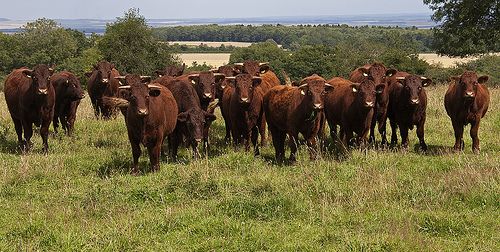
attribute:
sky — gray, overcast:
[0, 3, 442, 25]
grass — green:
[223, 174, 465, 244]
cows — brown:
[8, 46, 487, 159]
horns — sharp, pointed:
[114, 81, 164, 94]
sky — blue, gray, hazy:
[1, 0, 451, 30]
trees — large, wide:
[2, 4, 189, 87]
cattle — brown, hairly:
[214, 72, 274, 149]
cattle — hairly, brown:
[258, 72, 331, 152]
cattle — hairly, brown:
[325, 73, 381, 147]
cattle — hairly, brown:
[444, 71, 489, 150]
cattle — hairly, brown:
[387, 72, 430, 152]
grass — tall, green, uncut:
[0, 150, 498, 248]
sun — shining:
[3, 4, 494, 39]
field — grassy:
[0, 81, 484, 246]